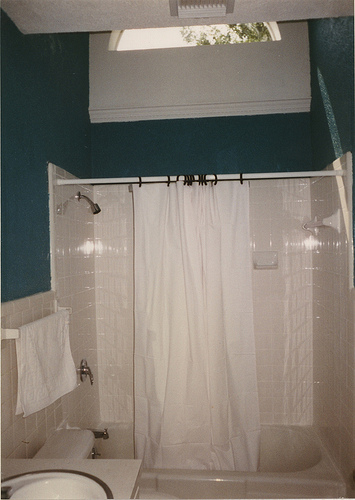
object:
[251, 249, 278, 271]
holder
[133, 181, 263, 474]
shower curtain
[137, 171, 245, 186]
curtain rings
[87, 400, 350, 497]
white tub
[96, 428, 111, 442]
water faucet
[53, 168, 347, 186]
rod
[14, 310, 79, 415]
white towel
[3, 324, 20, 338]
rack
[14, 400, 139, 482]
toilet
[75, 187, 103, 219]
chrome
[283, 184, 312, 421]
tile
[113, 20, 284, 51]
window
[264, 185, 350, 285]
bar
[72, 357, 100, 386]
handle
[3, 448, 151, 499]
counter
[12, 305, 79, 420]
towel/rod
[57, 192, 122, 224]
shower head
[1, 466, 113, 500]
sink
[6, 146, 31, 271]
wall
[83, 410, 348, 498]
bathtub